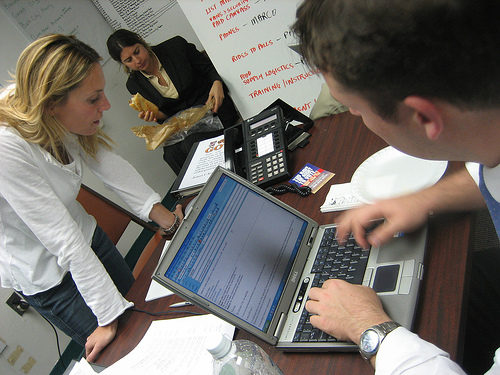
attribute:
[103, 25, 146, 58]
hair — dark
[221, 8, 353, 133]
writing — red and black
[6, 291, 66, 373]
outlet — black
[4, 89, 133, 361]
shirt — white, long sleeve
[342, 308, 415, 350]
wrist watch — silver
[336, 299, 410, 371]
watch — metal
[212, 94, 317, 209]
phone — black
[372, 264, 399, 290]
trackpad — black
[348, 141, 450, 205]
plate — paper, empty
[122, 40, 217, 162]
suit — black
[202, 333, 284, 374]
bottle — clear, plastic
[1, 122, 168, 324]
shirt — white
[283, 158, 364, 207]
planner — small, blue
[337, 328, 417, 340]
watch — silver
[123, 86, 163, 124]
sandwich — hoagie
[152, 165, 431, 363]
laptop — open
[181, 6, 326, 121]
erase board — dry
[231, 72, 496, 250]
desk — wooden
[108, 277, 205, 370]
paper — white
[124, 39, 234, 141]
jacket — black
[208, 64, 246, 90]
whiteboard — white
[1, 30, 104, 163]
hair — blonde